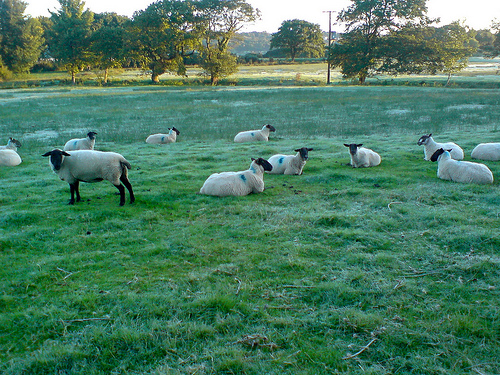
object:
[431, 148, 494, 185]
sheep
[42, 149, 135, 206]
sheep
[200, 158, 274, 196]
sheep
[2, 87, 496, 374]
grass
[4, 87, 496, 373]
an area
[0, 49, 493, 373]
field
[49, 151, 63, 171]
face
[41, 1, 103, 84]
tree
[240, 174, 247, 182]
mark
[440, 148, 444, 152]
ears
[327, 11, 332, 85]
pole